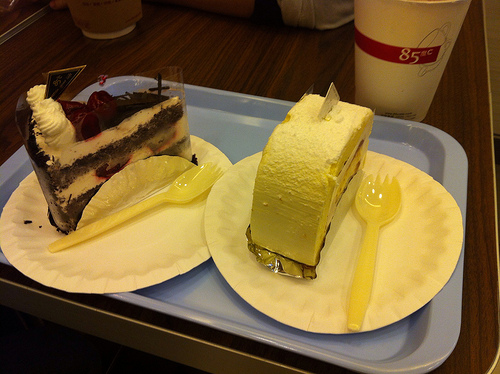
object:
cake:
[15, 82, 196, 231]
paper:
[75, 154, 201, 229]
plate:
[0, 131, 234, 294]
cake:
[244, 91, 374, 278]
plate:
[204, 148, 467, 334]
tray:
[2, 75, 469, 374]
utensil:
[348, 173, 399, 332]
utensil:
[46, 160, 228, 254]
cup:
[352, 0, 467, 122]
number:
[398, 48, 420, 65]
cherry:
[89, 90, 116, 117]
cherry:
[73, 109, 102, 138]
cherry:
[62, 100, 86, 117]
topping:
[27, 84, 75, 152]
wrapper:
[14, 65, 196, 236]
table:
[0, 4, 499, 374]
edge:
[189, 134, 231, 172]